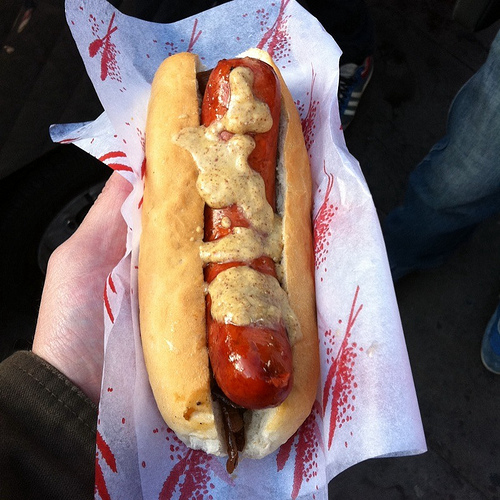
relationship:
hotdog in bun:
[202, 57, 293, 411] [136, 45, 319, 458]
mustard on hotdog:
[172, 67, 305, 343] [202, 57, 293, 411]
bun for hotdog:
[136, 45, 319, 458] [202, 57, 293, 411]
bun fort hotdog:
[136, 45, 319, 458] [202, 57, 293, 411]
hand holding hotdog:
[30, 170, 133, 407] [202, 57, 293, 411]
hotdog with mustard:
[202, 57, 293, 411] [172, 67, 305, 343]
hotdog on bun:
[202, 57, 293, 411] [136, 45, 319, 458]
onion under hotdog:
[212, 390, 250, 472] [202, 57, 293, 411]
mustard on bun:
[172, 67, 305, 343] [136, 45, 319, 458]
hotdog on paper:
[202, 57, 293, 411] [49, 0, 429, 499]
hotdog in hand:
[202, 57, 293, 411] [30, 170, 133, 407]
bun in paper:
[136, 45, 319, 458] [49, 0, 429, 499]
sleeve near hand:
[1, 347, 99, 499] [30, 170, 133, 407]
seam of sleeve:
[9, 349, 97, 433] [1, 347, 99, 499]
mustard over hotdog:
[172, 67, 305, 343] [202, 57, 293, 411]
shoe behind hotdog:
[338, 62, 375, 129] [202, 57, 293, 411]